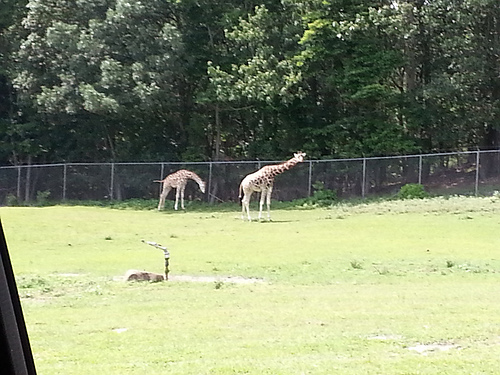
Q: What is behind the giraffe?
A: A fence.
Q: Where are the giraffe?
A: On a grassy field.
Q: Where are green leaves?
A: On trees.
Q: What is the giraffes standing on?
A: Grass.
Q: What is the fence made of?
A: Metal.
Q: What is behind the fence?
A: Trees.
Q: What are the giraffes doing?
A: Standing.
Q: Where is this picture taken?
A: Zoo.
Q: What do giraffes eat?
A: Leaves.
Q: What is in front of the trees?
A: Fence.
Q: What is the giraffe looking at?
A: Car.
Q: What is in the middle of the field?
A: Rock.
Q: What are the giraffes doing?
A: Standing.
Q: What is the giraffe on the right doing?
A: Watching the camera person.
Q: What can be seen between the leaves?
A: Brown branches.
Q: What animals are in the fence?
A: Giraffes.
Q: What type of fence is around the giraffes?
A: Metal chain link fence.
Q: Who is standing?
A: Giraffe.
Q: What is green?
A: Grass.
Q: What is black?
A: Corner of the picture.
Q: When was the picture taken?
A: Daytime.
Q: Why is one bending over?
A: To eat.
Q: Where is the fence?
A: Along the back of the yard.